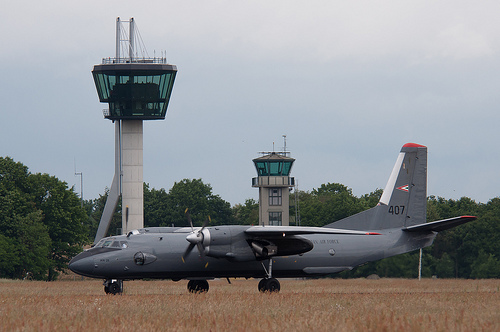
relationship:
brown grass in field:
[2, 275, 499, 329] [0, 273, 498, 330]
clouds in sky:
[195, 4, 496, 80] [3, 3, 497, 206]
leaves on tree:
[12, 197, 102, 268] [2, 154, 89, 288]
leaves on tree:
[1, 155, 94, 280] [0, 154, 95, 280]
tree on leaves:
[195, 178, 217, 193] [1, 147, 498, 295]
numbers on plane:
[381, 199, 411, 219] [64, 138, 477, 299]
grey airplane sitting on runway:
[72, 143, 479, 308] [4, 277, 499, 330]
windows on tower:
[93, 74, 170, 114] [244, 141, 303, 227]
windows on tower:
[93, 74, 170, 114] [88, 15, 177, 245]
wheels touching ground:
[104, 278, 294, 295] [63, 294, 468, 329]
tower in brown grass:
[88, 15, 177, 245] [2, 275, 499, 329]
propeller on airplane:
[181, 219, 226, 273] [75, 140, 472, 298]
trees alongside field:
[2, 158, 109, 281] [0, 273, 498, 330]